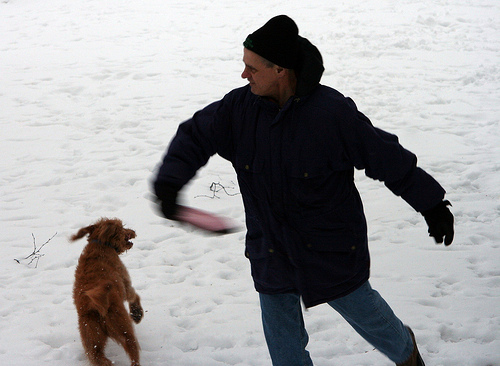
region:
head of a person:
[217, 17, 326, 117]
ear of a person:
[272, 53, 304, 77]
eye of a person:
[247, 60, 259, 73]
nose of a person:
[228, 60, 259, 82]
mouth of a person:
[237, 75, 264, 95]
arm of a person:
[143, 95, 257, 200]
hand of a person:
[415, 193, 464, 248]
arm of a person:
[339, 96, 461, 198]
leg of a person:
[262, 270, 300, 364]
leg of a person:
[332, 270, 398, 362]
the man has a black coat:
[185, 3, 465, 365]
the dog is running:
[43, 218, 142, 364]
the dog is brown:
[49, 213, 168, 353]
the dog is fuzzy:
[51, 220, 161, 365]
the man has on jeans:
[257, 298, 443, 364]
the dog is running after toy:
[163, 203, 260, 245]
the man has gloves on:
[427, 190, 465, 246]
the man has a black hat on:
[229, 0, 306, 62]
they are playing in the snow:
[38, 239, 365, 359]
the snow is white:
[146, 255, 251, 348]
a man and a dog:
[58, 17, 475, 363]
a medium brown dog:
[22, 174, 170, 359]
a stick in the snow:
[7, 209, 63, 285]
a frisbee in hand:
[148, 163, 253, 260]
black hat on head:
[233, 16, 317, 56]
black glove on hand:
[410, 199, 473, 250]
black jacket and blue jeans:
[129, 52, 390, 364]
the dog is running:
[52, 168, 180, 348]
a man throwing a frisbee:
[121, 19, 481, 365]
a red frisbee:
[146, 156, 258, 253]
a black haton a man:
[242, 13, 305, 69]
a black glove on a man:
[424, 200, 456, 244]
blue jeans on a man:
[254, 281, 418, 363]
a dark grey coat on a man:
[163, 67, 444, 305]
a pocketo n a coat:
[302, 228, 363, 290]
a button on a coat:
[304, 239, 315, 250]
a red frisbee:
[160, 199, 234, 239]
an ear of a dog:
[67, 221, 87, 244]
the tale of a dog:
[84, 277, 114, 323]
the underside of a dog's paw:
[126, 300, 147, 324]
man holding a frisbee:
[142, 20, 432, 361]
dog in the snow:
[61, 199, 153, 360]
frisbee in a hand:
[155, 174, 240, 256]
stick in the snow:
[11, 223, 51, 274]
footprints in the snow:
[440, 313, 499, 352]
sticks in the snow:
[196, 171, 232, 203]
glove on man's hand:
[425, 159, 462, 262]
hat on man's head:
[230, 12, 315, 70]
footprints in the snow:
[25, 38, 102, 132]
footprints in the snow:
[405, 10, 477, 84]